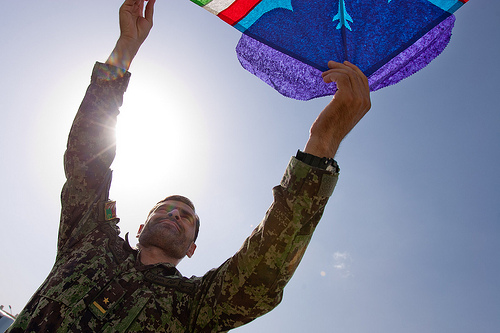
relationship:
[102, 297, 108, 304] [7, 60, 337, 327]
star on uniform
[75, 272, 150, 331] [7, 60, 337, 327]
yellow stripe on uniform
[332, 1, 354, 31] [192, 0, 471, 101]
plane image on fabric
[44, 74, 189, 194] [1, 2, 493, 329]
sun shining in sky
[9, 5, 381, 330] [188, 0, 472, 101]
soldier holding fabric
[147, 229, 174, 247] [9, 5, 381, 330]
chin of a soldier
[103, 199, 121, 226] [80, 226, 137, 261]
badge on shoulder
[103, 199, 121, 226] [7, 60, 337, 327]
badge on uniform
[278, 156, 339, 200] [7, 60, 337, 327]
cuff of uniform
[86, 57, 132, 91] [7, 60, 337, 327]
cuff of uniform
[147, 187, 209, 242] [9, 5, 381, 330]
hair on soldier